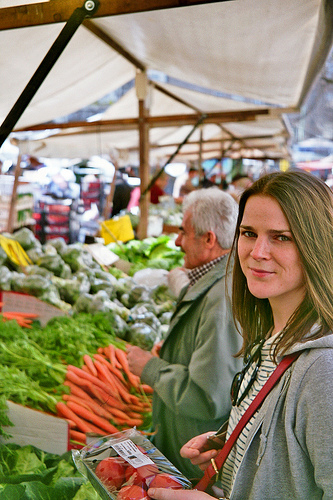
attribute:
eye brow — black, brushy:
[266, 228, 290, 235]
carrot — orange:
[82, 352, 97, 380]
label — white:
[110, 437, 156, 467]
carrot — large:
[101, 348, 116, 358]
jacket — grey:
[139, 256, 247, 480]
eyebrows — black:
[171, 221, 199, 237]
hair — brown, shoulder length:
[220, 162, 332, 368]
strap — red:
[189, 344, 306, 492]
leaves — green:
[2, 442, 94, 496]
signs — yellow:
[4, 202, 135, 253]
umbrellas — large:
[1, 2, 330, 163]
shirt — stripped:
[213, 346, 299, 479]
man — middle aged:
[130, 204, 267, 451]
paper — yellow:
[101, 214, 140, 248]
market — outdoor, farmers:
[0, 86, 204, 498]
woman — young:
[203, 156, 331, 424]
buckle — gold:
[211, 451, 225, 475]